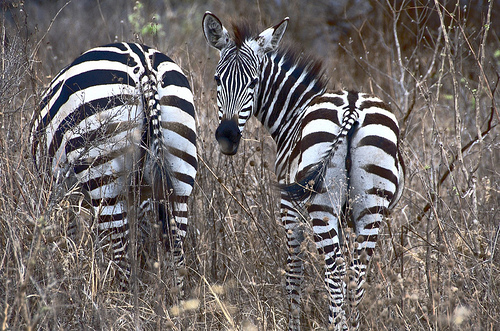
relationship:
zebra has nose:
[200, 9, 408, 331] [215, 118, 243, 155]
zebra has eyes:
[200, 9, 408, 331] [213, 75, 260, 90]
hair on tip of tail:
[275, 160, 326, 211] [277, 109, 359, 206]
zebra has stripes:
[200, 9, 408, 331] [216, 42, 405, 329]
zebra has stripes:
[27, 40, 201, 304] [30, 40, 199, 301]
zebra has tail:
[200, 9, 408, 331] [277, 109, 359, 206]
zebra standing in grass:
[200, 9, 408, 331] [0, 76, 499, 330]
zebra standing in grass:
[27, 40, 201, 304] [0, 76, 499, 330]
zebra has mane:
[200, 9, 408, 331] [231, 16, 342, 92]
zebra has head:
[200, 9, 408, 331] [201, 9, 290, 155]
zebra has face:
[200, 9, 408, 331] [213, 66, 262, 157]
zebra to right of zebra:
[200, 9, 408, 331] [27, 40, 201, 304]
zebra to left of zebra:
[27, 40, 201, 304] [200, 9, 408, 331]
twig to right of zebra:
[401, 77, 499, 242] [200, 9, 408, 331]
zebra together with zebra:
[200, 9, 408, 331] [27, 40, 201, 304]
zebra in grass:
[200, 9, 408, 331] [0, 76, 499, 330]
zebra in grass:
[27, 40, 201, 304] [0, 76, 499, 330]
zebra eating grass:
[27, 40, 201, 304] [0, 76, 499, 330]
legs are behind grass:
[74, 158, 197, 296] [0, 76, 499, 330]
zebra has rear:
[200, 9, 408, 331] [300, 90, 400, 200]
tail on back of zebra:
[277, 109, 359, 206] [200, 9, 408, 331]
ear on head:
[254, 16, 290, 55] [201, 9, 290, 155]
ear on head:
[201, 9, 234, 49] [201, 9, 290, 155]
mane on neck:
[231, 16, 342, 92] [259, 51, 327, 136]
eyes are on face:
[213, 75, 260, 90] [213, 66, 262, 157]